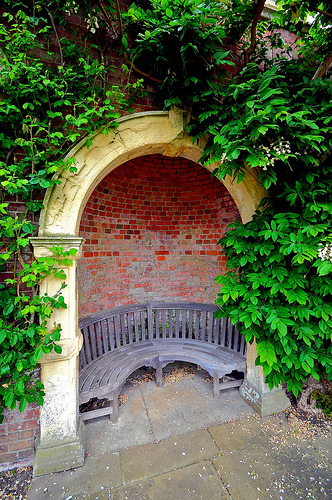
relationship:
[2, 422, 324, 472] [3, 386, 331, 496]
petals on walkway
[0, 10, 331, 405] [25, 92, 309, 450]
leaves surround entrance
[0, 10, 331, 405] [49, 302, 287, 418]
leaves under bench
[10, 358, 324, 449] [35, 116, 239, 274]
bottom of arch discolored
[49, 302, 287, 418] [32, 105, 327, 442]
bench inside arch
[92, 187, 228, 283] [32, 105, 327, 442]
brick inside arch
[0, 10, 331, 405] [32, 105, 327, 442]
leaves at archway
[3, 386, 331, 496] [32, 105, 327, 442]
flloor leading up to arch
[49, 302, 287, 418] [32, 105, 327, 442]
bench at arch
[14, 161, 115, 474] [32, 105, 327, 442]
pillar of archway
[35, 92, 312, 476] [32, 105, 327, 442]
stones at arch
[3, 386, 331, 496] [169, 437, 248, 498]
area paved with stone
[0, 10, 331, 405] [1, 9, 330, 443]
vines are growing up wall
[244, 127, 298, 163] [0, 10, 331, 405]
flowers are blooming on the plant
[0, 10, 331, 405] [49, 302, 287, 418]
greenery around bench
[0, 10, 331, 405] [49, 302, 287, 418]
leaves over seating area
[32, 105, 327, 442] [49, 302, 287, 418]
arch over seat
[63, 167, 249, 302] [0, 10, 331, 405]
wall behind trees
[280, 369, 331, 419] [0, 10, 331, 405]
root growing from trees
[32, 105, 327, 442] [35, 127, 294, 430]
archway needs paint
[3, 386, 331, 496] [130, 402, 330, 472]
area needs sweeping